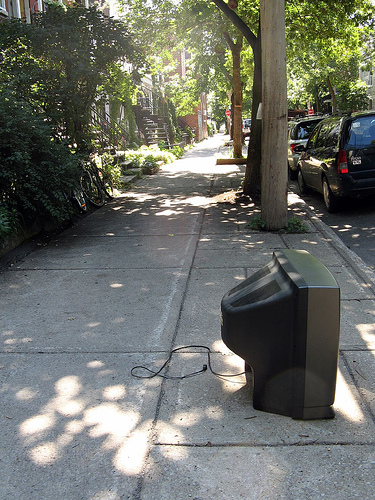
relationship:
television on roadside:
[222, 249, 343, 422] [160, 152, 216, 500]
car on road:
[297, 112, 374, 208] [334, 214, 375, 244]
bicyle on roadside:
[79, 146, 121, 204] [160, 152, 216, 500]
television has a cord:
[222, 249, 343, 422] [128, 343, 214, 383]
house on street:
[3, 1, 37, 17] [167, 125, 370, 276]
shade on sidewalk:
[137, 173, 235, 200] [160, 152, 216, 500]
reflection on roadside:
[170, 156, 212, 175] [160, 152, 216, 500]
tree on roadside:
[196, 1, 246, 156] [160, 152, 216, 500]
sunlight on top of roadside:
[170, 156, 212, 175] [160, 152, 216, 500]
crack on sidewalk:
[176, 288, 189, 331] [160, 152, 216, 500]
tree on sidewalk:
[196, 1, 246, 156] [160, 152, 216, 500]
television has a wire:
[222, 249, 343, 422] [128, 343, 214, 383]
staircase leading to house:
[123, 96, 175, 150] [106, 22, 158, 89]